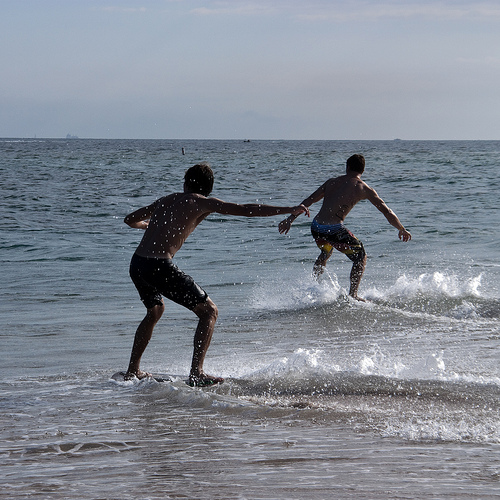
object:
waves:
[210, 253, 439, 445]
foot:
[122, 369, 147, 383]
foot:
[183, 372, 220, 387]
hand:
[277, 216, 295, 234]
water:
[10, 133, 477, 438]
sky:
[19, 15, 499, 160]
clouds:
[174, 24, 281, 111]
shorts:
[129, 259, 208, 312]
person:
[277, 153, 413, 302]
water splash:
[244, 260, 372, 317]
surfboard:
[104, 359, 243, 392]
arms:
[192, 192, 293, 217]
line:
[12, 175, 82, 216]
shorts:
[308, 219, 366, 257]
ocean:
[5, 139, 499, 442]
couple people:
[124, 154, 412, 387]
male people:
[123, 162, 307, 386]